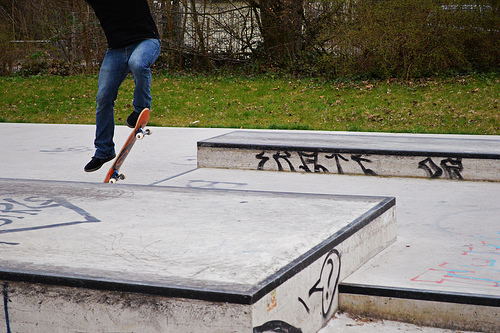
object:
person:
[81, 1, 162, 173]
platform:
[197, 130, 499, 181]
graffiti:
[253, 152, 378, 177]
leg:
[91, 50, 125, 154]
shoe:
[80, 148, 118, 174]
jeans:
[93, 36, 164, 159]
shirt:
[85, 1, 160, 54]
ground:
[0, 74, 499, 332]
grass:
[0, 75, 499, 136]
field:
[0, 70, 499, 135]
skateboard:
[101, 107, 155, 185]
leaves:
[383, 90, 394, 96]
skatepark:
[0, 122, 499, 332]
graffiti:
[413, 155, 463, 181]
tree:
[252, 0, 308, 68]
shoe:
[126, 108, 141, 128]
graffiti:
[308, 248, 342, 319]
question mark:
[323, 259, 335, 302]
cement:
[0, 206, 499, 333]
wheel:
[134, 132, 144, 140]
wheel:
[144, 128, 153, 135]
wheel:
[108, 178, 116, 185]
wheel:
[120, 172, 125, 180]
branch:
[156, 4, 261, 20]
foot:
[84, 148, 119, 172]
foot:
[125, 110, 142, 129]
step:
[0, 176, 398, 332]